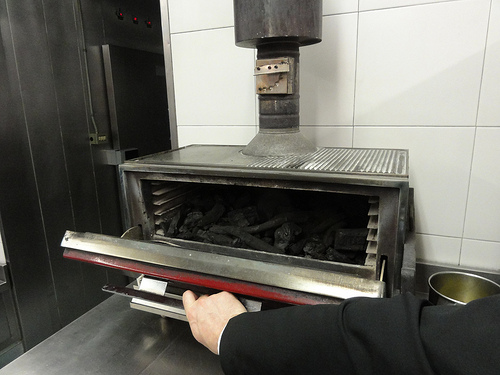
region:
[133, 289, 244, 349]
a hand on a handle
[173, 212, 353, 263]
sticks of wood in stove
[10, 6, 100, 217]
black panels on the wall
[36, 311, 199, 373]
grey shiny metal on the floor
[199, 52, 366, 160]
a metal pipe running out of stove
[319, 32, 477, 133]
a white shiny board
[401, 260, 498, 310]
a silver bowl on ground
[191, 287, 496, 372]
the black sleeve on a arm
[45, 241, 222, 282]
a red handle on a stove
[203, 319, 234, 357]
a piece of a white shirt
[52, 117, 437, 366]
charcoal heater with door open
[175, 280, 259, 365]
right hand of a man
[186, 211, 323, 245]
charcoal in a heater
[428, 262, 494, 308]
bowl by a heater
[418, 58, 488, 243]
white tile on a wall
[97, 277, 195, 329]
handle of a heater door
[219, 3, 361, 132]
pipe to a heater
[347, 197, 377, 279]
racks in a heater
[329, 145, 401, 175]
top of a heater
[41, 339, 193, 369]
steel counter top where heater is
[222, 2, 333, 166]
stove pipe of oven cooker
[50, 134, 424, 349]
oven cooker with wood and charcoal inside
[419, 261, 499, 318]
stainless steel bowl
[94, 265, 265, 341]
silver handle on cooker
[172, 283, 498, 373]
man's right hand and arm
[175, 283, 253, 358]
man's white right hand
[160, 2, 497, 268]
white tiles on wall of kitchen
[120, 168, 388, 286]
inside of oven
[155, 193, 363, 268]
black charcoal and burnt wood in oven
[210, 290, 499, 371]
right arm of man wearing black suit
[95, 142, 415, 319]
a small little oven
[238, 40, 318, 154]
the pipe of an oven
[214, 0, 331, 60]
the pipe of an oven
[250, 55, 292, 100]
a piece of brown metal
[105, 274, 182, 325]
the handle of an oven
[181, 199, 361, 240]
Burnt food in toaster oven.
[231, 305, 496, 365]
Black sleeve on arm.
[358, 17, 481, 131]
White square wall tile.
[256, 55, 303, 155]
Metal piping attached to oven.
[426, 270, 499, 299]
Silver pot in the corner.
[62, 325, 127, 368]
stainless steel counter top.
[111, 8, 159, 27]
Three red lights in walk way.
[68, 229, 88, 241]
Burnt part on toaster oven.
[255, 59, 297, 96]
old metal oven fixture.